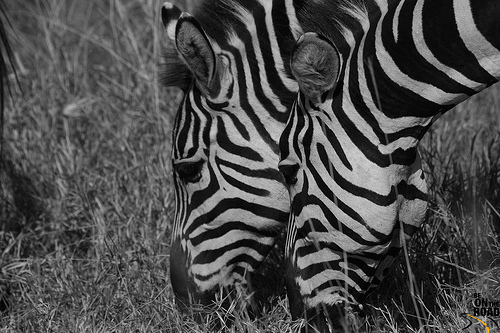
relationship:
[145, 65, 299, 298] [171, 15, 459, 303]
face on zebra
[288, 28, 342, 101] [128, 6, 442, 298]
ear on zebra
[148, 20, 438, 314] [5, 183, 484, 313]
heads in grass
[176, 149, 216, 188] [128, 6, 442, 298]
eyes on zebra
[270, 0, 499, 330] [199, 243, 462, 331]
zebra eating grasses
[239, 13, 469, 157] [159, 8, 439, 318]
neck of zebra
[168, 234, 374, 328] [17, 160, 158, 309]
mouths in grass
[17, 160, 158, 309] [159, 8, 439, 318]
grass of zebra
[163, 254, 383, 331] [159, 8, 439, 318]
nose of zebra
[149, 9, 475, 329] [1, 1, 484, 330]
zebra eating grass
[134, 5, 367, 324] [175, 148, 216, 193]
zebra has eyes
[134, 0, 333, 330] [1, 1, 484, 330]
zebra grazing in grass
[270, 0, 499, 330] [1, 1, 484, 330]
zebra grazing in grass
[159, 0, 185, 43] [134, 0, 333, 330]
ear belonging to zebra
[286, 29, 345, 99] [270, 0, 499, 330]
ear belonging to zebra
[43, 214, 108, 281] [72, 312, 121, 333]
black and white grass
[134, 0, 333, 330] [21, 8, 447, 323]
zebra eating grass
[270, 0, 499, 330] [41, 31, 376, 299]
zebra on grass